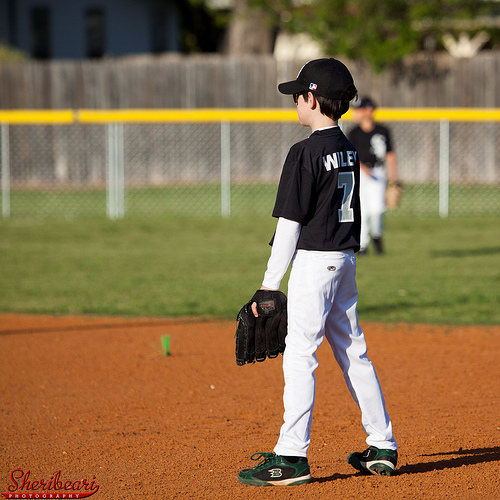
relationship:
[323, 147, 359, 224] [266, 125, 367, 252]
writing on jersey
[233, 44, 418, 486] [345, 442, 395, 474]
boy wearing shoe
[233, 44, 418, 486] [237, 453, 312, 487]
boy wearing shoe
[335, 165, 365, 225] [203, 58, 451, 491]
number on boy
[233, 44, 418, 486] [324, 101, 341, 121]
boy has hair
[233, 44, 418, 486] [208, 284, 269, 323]
boy with ball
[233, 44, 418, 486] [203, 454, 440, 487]
boy wearing cleats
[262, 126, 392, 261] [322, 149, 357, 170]
shirt has name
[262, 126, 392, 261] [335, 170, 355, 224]
shirt has number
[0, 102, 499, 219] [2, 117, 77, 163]
fence has square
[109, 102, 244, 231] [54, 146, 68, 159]
fence has square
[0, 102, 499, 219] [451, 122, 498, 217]
fence has square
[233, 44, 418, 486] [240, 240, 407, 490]
boy wearing pants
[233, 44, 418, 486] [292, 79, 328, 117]
boy has ear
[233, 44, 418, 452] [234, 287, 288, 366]
boy holding baseball glove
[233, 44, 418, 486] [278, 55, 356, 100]
boy has on hat